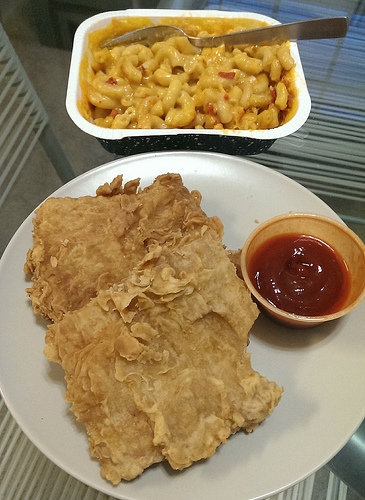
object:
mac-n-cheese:
[91, 30, 288, 128]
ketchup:
[247, 232, 351, 317]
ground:
[37, 59, 59, 99]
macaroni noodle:
[274, 81, 289, 112]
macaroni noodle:
[162, 78, 181, 114]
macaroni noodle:
[80, 79, 119, 109]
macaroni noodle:
[230, 48, 264, 76]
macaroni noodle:
[194, 89, 233, 124]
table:
[319, 0, 365, 180]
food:
[77, 17, 299, 130]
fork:
[100, 15, 348, 51]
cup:
[240, 213, 365, 331]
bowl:
[64, 8, 311, 158]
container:
[65, 8, 311, 158]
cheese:
[113, 53, 262, 103]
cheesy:
[88, 25, 297, 122]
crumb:
[254, 219, 259, 224]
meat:
[43, 224, 281, 486]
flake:
[218, 72, 235, 79]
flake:
[207, 103, 212, 112]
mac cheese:
[175, 51, 268, 115]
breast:
[23, 172, 283, 487]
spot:
[187, 134, 205, 147]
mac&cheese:
[106, 41, 166, 119]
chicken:
[23, 172, 284, 486]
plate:
[0, 150, 365, 500]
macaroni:
[87, 25, 295, 129]